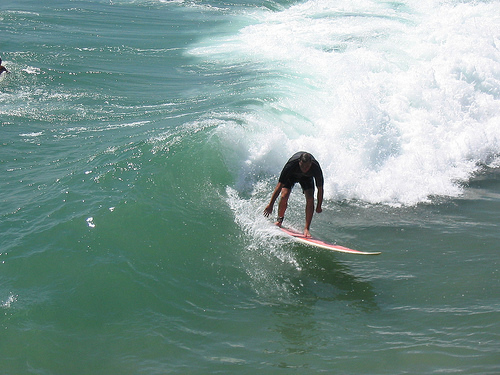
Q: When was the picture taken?
A: Daytime.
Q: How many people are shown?
A: One.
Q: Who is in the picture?
A: A surfer.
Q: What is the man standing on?
A: A surfboard.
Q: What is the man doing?
A: Surfing.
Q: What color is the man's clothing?
A: Black.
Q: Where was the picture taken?
A: Ocean.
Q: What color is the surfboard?
A: Orange and white.